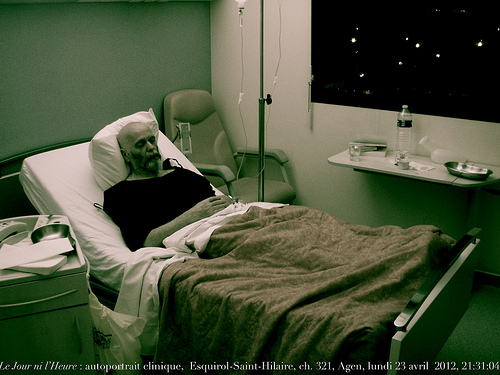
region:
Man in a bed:
[97, 115, 444, 298]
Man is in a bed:
[101, 118, 446, 297]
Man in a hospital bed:
[102, 120, 452, 290]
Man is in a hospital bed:
[102, 121, 449, 283]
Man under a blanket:
[86, 121, 254, 249]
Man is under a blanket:
[102, 120, 240, 249]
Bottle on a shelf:
[392, 99, 415, 161]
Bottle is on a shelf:
[390, 94, 417, 160]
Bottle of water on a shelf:
[393, 102, 416, 162]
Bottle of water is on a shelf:
[393, 98, 417, 160]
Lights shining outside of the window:
[346, 23, 484, 93]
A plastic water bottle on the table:
[392, 103, 418, 157]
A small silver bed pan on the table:
[442, 157, 494, 183]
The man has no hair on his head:
[114, 120, 156, 147]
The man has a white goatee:
[142, 151, 166, 173]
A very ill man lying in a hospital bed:
[95, 112, 463, 287]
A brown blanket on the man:
[210, 204, 438, 344]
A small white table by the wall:
[328, 133, 498, 196]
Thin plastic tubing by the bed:
[225, 3, 260, 197]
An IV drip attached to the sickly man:
[209, 0, 286, 207]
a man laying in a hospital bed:
[109, 126, 411, 309]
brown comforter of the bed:
[196, 230, 401, 341]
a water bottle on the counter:
[395, 106, 415, 157]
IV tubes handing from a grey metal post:
[229, 1, 287, 193]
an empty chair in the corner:
[163, 82, 302, 205]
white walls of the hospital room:
[297, 137, 331, 212]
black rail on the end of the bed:
[390, 229, 477, 334]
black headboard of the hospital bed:
[1, 144, 28, 213]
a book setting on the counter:
[348, 139, 390, 161]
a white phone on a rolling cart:
[1, 216, 31, 244]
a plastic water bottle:
[392, 102, 419, 157]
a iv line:
[220, 16, 250, 225]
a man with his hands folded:
[187, 185, 236, 226]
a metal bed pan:
[429, 159, 493, 184]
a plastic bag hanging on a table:
[80, 294, 135, 374]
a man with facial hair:
[127, 146, 163, 174]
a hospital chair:
[182, 68, 255, 200]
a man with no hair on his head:
[113, 121, 151, 148]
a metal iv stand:
[248, 17, 268, 202]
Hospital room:
[1, 0, 498, 373]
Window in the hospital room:
[310, 0, 497, 119]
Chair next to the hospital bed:
[160, 88, 296, 206]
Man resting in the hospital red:
[101, 120, 458, 292]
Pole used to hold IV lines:
[254, 0, 273, 205]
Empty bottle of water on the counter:
[397, 100, 412, 157]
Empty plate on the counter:
[446, 154, 493, 180]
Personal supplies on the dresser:
[2, 213, 78, 280]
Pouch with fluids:
[234, 0, 251, 12]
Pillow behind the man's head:
[89, 109, 164, 189]